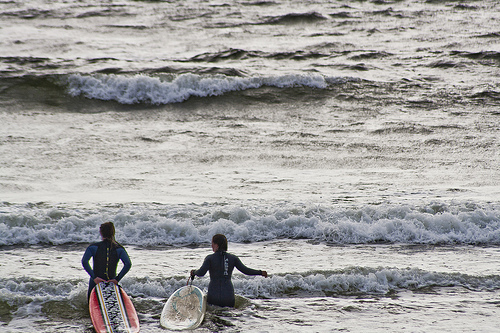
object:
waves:
[3, 206, 489, 247]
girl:
[81, 220, 132, 306]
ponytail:
[106, 229, 118, 243]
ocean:
[5, 4, 495, 332]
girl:
[187, 232, 273, 309]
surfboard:
[157, 283, 208, 331]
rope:
[187, 272, 198, 288]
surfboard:
[87, 283, 145, 332]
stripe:
[94, 280, 129, 330]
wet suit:
[191, 250, 272, 310]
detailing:
[103, 243, 111, 279]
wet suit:
[80, 240, 135, 306]